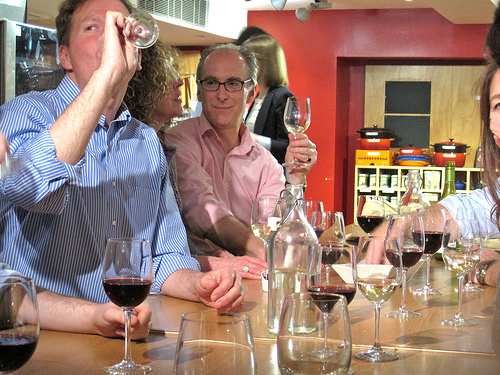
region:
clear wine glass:
[273, 95, 320, 150]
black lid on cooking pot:
[440, 135, 464, 144]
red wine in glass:
[96, 275, 176, 314]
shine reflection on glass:
[448, 237, 464, 254]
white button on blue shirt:
[104, 180, 130, 193]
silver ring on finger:
[237, 265, 252, 274]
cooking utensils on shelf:
[351, 115, 487, 174]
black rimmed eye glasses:
[199, 68, 270, 94]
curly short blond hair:
[141, 51, 193, 98]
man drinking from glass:
[51, 10, 168, 87]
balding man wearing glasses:
[185, 37, 346, 234]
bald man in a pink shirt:
[181, 21, 313, 233]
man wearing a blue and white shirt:
[16, 8, 197, 328]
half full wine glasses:
[13, 190, 479, 350]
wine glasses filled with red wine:
[35, 213, 475, 336]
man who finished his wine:
[175, 30, 327, 267]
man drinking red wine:
[18, 3, 213, 194]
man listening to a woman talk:
[126, 21, 293, 233]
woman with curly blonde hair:
[121, 19, 189, 146]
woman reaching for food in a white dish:
[344, 42, 499, 302]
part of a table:
[431, 350, 443, 367]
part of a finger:
[225, 280, 231, 287]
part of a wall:
[358, 102, 370, 121]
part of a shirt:
[107, 178, 121, 210]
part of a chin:
[215, 120, 223, 122]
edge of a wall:
[355, 105, 362, 125]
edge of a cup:
[209, 312, 224, 339]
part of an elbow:
[33, 193, 50, 207]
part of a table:
[415, 342, 419, 349]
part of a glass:
[209, 336, 236, 367]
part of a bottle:
[289, 245, 313, 288]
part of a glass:
[218, 330, 253, 369]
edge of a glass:
[307, 289, 324, 316]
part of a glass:
[304, 308, 325, 338]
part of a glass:
[399, 200, 429, 239]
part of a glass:
[302, 248, 322, 275]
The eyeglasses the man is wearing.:
[201, 77, 248, 88]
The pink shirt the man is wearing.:
[173, 120, 285, 225]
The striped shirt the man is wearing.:
[3, 83, 190, 289]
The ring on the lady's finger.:
[241, 265, 248, 275]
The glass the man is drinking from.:
[107, 10, 157, 55]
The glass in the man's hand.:
[287, 90, 309, 170]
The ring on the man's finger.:
[307, 155, 312, 161]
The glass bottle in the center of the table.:
[269, 178, 319, 334]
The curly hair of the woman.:
[140, 44, 165, 126]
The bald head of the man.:
[194, 41, 250, 72]